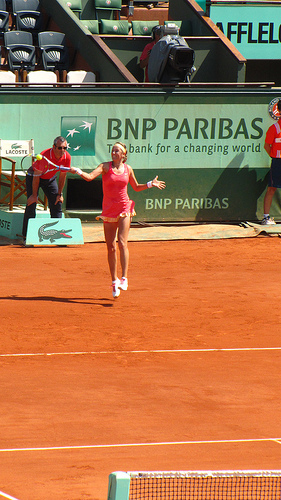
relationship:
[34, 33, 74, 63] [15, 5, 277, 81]
chair in stands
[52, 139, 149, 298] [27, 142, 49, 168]
player hits ball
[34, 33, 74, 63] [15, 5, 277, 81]
chair rests in stands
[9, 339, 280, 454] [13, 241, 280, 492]
lines on court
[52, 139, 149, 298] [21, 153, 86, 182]
player holds racket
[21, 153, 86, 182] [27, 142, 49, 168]
racket hits ball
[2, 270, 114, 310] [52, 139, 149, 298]
shadow under player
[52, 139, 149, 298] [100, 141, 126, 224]
player wears dress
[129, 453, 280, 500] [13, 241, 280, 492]
net sits on court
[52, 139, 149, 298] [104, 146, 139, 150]
player wears headband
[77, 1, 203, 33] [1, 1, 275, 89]
seats in stands